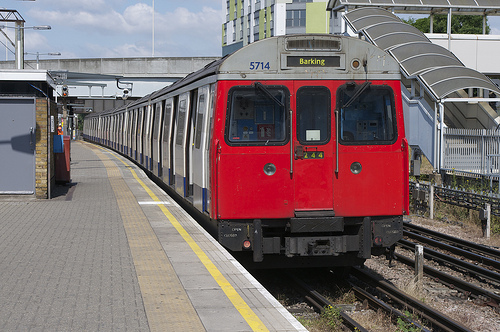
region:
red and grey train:
[110, 95, 407, 241]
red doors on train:
[217, 75, 410, 216]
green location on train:
[280, 53, 342, 75]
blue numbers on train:
[240, 59, 280, 81]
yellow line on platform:
[75, 142, 259, 327]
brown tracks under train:
[309, 244, 472, 330]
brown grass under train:
[335, 262, 481, 315]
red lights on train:
[230, 222, 407, 261]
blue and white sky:
[53, 2, 200, 47]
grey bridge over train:
[48, 47, 188, 72]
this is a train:
[44, 35, 435, 266]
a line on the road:
[212, 279, 257, 328]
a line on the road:
[200, 250, 255, 303]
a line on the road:
[152, 191, 200, 261]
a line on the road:
[135, 170, 191, 238]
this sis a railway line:
[370, 275, 437, 316]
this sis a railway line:
[432, 231, 483, 289]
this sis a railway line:
[415, 227, 460, 284]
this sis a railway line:
[313, 285, 341, 321]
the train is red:
[285, 170, 373, 205]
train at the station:
[0, 56, 422, 277]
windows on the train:
[250, 88, 393, 142]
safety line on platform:
[139, 225, 258, 327]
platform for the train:
[21, 185, 208, 323]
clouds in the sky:
[76, 0, 192, 45]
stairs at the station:
[372, 43, 482, 176]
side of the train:
[45, 91, 181, 156]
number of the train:
[194, 46, 280, 73]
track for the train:
[295, 278, 436, 324]